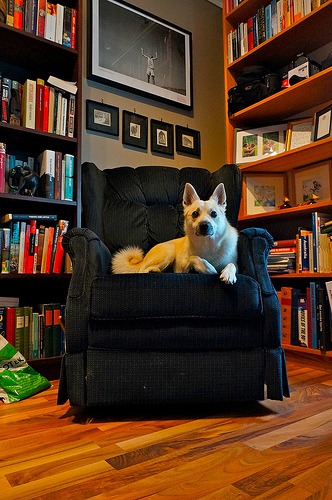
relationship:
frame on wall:
[84, 98, 120, 139] [83, 0, 225, 172]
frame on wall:
[121, 110, 149, 151] [83, 0, 225, 172]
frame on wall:
[150, 117, 175, 158] [83, 0, 225, 172]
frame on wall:
[175, 122, 202, 160] [83, 0, 225, 172]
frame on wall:
[87, 1, 195, 116] [83, 0, 225, 172]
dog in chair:
[110, 178, 238, 285] [54, 156, 293, 414]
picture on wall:
[176, 122, 200, 153] [75, 0, 232, 176]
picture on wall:
[83, 0, 192, 112] [83, 0, 225, 172]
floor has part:
[152, 427, 265, 492] [132, 425, 305, 498]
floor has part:
[0, 352, 331, 498] [191, 417, 293, 467]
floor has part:
[0, 352, 331, 498] [212, 437, 228, 453]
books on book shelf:
[1, 1, 76, 378] [1, 2, 87, 379]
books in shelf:
[231, 5, 328, 338] [222, 54, 298, 222]